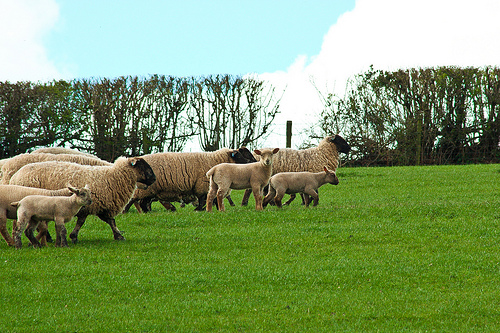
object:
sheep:
[269, 167, 339, 211]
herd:
[1, 132, 355, 247]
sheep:
[205, 149, 278, 210]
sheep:
[9, 186, 92, 245]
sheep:
[271, 135, 349, 172]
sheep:
[10, 158, 157, 241]